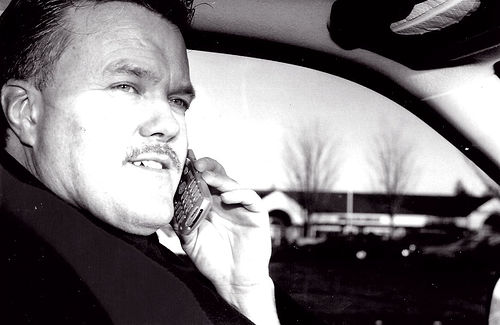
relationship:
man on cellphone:
[0, 0, 281, 325] [171, 148, 213, 238]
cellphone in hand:
[171, 148, 213, 238] [179, 157, 272, 277]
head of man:
[1, 0, 195, 237] [0, 0, 281, 325]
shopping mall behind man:
[254, 192, 500, 246] [0, 0, 281, 325]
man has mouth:
[0, 0, 281, 325] [128, 151, 174, 179]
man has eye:
[0, 0, 281, 325] [106, 83, 141, 97]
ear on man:
[0, 79, 39, 148] [0, 0, 281, 325]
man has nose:
[0, 0, 281, 325] [142, 96, 180, 143]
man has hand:
[0, 0, 281, 325] [179, 157, 272, 277]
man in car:
[0, 0, 281, 325] [0, 0, 499, 324]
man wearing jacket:
[0, 0, 281, 325] [0, 148, 257, 324]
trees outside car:
[285, 127, 417, 240] [0, 0, 499, 324]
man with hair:
[0, 0, 281, 325] [0, 1, 195, 84]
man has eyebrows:
[0, 0, 281, 325] [110, 65, 197, 97]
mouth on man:
[128, 151, 174, 179] [0, 0, 281, 325]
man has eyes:
[0, 0, 281, 325] [107, 82, 190, 108]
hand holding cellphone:
[179, 157, 272, 277] [171, 148, 213, 238]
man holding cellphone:
[0, 0, 281, 325] [171, 148, 213, 238]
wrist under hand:
[212, 269, 274, 307] [179, 157, 272, 277]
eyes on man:
[107, 82, 190, 108] [0, 0, 281, 325]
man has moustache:
[0, 0, 281, 325] [126, 144, 182, 172]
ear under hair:
[0, 79, 39, 148] [0, 1, 195, 84]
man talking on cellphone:
[0, 0, 281, 325] [171, 148, 213, 238]